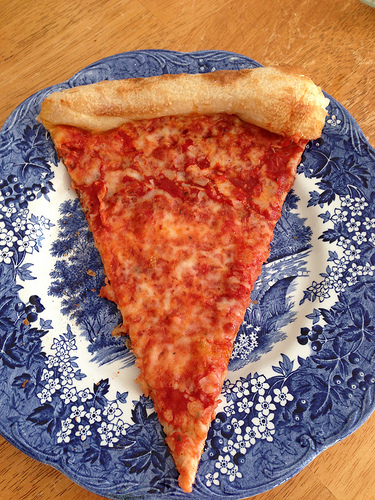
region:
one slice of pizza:
[73, 98, 272, 452]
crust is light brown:
[51, 34, 310, 114]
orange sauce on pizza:
[76, 130, 268, 449]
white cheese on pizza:
[94, 153, 310, 406]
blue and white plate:
[37, 55, 360, 498]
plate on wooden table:
[33, 0, 358, 498]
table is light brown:
[26, 12, 319, 90]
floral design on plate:
[5, 55, 367, 412]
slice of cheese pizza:
[61, 93, 297, 431]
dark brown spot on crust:
[93, 50, 305, 134]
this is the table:
[329, 471, 349, 485]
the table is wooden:
[320, 463, 353, 488]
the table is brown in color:
[323, 456, 365, 486]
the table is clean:
[322, 463, 351, 488]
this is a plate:
[28, 274, 72, 373]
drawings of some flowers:
[227, 391, 279, 435]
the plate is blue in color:
[278, 434, 292, 454]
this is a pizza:
[39, 62, 324, 488]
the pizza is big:
[126, 181, 219, 269]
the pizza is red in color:
[149, 157, 197, 175]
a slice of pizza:
[40, 78, 329, 339]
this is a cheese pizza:
[35, 81, 319, 270]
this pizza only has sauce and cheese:
[96, 224, 272, 485]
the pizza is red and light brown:
[60, 124, 309, 319]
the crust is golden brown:
[51, 68, 352, 127]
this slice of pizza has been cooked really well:
[37, 89, 309, 349]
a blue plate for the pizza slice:
[260, 232, 358, 386]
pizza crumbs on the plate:
[4, 247, 127, 361]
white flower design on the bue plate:
[215, 367, 287, 477]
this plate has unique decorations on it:
[26, 139, 342, 347]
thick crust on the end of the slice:
[27, 68, 333, 140]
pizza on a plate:
[0, 48, 373, 499]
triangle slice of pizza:
[32, 66, 330, 499]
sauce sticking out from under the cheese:
[165, 388, 193, 412]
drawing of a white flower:
[69, 404, 84, 422]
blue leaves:
[312, 209, 335, 226]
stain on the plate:
[111, 369, 122, 381]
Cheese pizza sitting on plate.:
[1, 47, 374, 498]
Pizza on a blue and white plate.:
[1, 47, 374, 498]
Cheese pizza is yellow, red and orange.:
[34, 63, 330, 493]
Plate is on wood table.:
[0, 1, 372, 498]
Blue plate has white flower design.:
[0, 48, 373, 498]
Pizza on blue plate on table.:
[0, 1, 373, 499]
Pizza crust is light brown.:
[33, 62, 328, 143]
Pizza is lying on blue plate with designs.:
[1, 47, 374, 499]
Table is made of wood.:
[1, 0, 374, 498]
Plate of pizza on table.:
[1, 0, 374, 499]